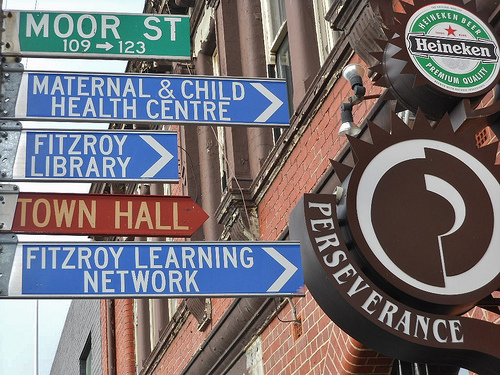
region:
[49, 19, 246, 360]
These are street signs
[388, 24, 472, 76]
This is a sign of Heinenken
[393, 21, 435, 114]
The sign is very round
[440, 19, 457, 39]
This is a star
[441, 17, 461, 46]
The star is red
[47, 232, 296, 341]
The sign is blue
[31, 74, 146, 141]
The sign is made of steel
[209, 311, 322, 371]
This is a building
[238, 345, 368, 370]
The building is brick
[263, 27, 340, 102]
This is a window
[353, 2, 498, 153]
A green and white Heineken beer sign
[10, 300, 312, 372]
Brick building with windows in the background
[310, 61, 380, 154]
Spot lights between signs and building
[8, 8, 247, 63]
Street sign saying Moor St. 109-123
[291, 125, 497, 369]
A brown and white sign saying Preservance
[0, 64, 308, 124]
Sign saying Maternal & Child Health Center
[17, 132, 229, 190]
Blue and white sigh directing to Fitzroy Library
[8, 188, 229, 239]
Red and white sign which directs to Town Hall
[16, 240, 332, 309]
Blue and white sign directing to Fitzroy Learing Network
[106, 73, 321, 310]
All signs directing to the right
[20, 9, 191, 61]
a green and white street sign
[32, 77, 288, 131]
a blue and white business sign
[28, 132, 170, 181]
a blue and white business sign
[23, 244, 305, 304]
a blue and white business sign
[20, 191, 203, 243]
a red and tan government sign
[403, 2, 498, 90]
an advertisement for beer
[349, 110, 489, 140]
brown spikes on a sign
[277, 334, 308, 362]
red bricks in the wall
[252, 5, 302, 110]
a window in a building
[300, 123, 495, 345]
a fancy brown and white sign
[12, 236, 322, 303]
BLUE METAL STREET SIGN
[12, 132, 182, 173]
BLUE METAL STREET SIGN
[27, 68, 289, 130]
BLUE METAL STREET SIGN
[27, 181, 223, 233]
RED METAL STREET SIGN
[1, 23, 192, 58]
GREEN METAL STREET SIGN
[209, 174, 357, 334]
RED BRICKS ON WALL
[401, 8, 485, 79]
ROUND HEINEKEN SIGN ON BUILDING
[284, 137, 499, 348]
BROWN AND WHITE SIGN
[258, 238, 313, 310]
WHITE ARROW ON SIGN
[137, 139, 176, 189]
WHITE ARROW ON SIGN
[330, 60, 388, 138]
lights attached to a brick building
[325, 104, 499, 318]
round brown and white sign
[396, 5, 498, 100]
sign for heineken beer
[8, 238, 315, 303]
blue sign at the bottom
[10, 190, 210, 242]
red town hall sign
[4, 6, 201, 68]
green sign for moor street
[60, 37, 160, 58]
numbers on the moor street sign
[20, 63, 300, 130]
blue sign for the health centre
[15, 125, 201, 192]
blue sign for the library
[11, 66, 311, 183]
two adjacent blue signs